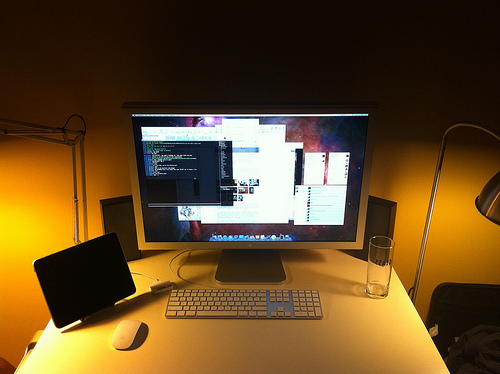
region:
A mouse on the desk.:
[109, 312, 146, 350]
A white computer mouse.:
[109, 311, 146, 356]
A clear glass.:
[367, 229, 394, 306]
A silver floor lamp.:
[408, 103, 499, 316]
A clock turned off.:
[28, 227, 135, 325]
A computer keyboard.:
[165, 284, 331, 326]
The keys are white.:
[166, 286, 323, 320]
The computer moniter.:
[120, 98, 364, 250]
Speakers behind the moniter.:
[94, 184, 403, 273]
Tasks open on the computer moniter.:
[137, 119, 350, 238]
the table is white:
[193, 268, 286, 355]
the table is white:
[206, 164, 416, 372]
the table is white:
[368, 332, 402, 372]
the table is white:
[291, 255, 386, 372]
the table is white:
[308, 211, 404, 341]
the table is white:
[328, 248, 408, 370]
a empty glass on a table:
[363, 233, 398, 300]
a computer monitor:
[126, 106, 370, 251]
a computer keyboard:
[158, 278, 327, 320]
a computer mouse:
[106, 317, 151, 352]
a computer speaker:
[98, 194, 140, 236]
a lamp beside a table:
[443, 115, 498, 232]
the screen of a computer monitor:
[145, 134, 345, 214]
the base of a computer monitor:
[210, 244, 293, 286]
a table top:
[386, 303, 435, 370]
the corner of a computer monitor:
[353, 103, 375, 128]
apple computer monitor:
[123, 104, 367, 249]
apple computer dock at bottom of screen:
[208, 228, 293, 243]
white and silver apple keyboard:
[168, 284, 325, 320]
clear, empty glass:
[364, 233, 395, 298]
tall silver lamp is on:
[407, 120, 499, 301]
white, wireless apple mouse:
[110, 316, 145, 350]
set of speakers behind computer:
[99, 192, 396, 262]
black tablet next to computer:
[33, 230, 135, 327]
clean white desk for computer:
[20, 242, 447, 371]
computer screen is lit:
[136, 113, 367, 240]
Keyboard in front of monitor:
[163, 286, 324, 321]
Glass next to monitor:
[364, 235, 394, 297]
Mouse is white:
[110, 312, 144, 349]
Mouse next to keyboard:
[112, 314, 142, 349]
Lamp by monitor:
[401, 121, 498, 313]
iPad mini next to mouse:
[28, 230, 134, 325]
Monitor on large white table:
[116, 105, 373, 285]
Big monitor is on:
[123, 95, 373, 281]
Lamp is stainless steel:
[405, 116, 497, 321]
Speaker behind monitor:
[348, 187, 398, 263]